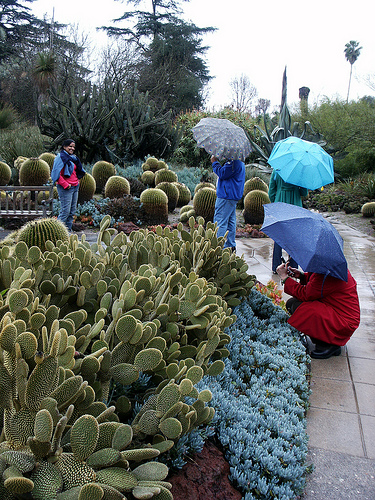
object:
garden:
[0, 214, 315, 499]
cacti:
[113, 311, 136, 345]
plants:
[0, 412, 175, 498]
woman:
[275, 250, 361, 361]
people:
[51, 127, 86, 231]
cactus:
[8, 286, 27, 316]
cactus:
[31, 406, 52, 443]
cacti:
[68, 411, 100, 463]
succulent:
[164, 286, 323, 497]